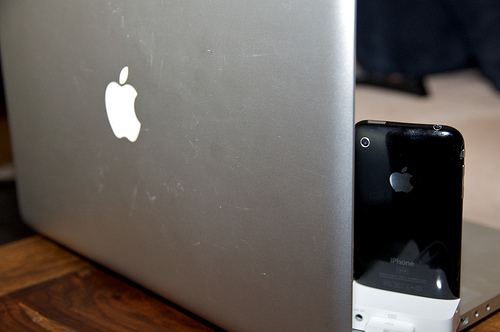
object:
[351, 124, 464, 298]
reflections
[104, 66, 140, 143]
apple logo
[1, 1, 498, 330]
computer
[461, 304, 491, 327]
ports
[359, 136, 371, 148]
camera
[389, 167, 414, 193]
apple image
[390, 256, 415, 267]
writing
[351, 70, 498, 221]
flooring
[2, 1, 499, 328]
room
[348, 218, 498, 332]
base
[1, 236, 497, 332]
table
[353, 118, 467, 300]
cell phone